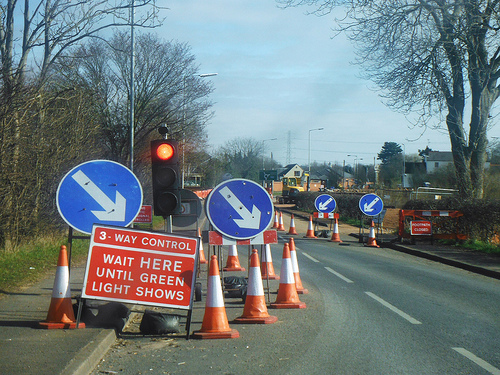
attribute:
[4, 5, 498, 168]
sky — blue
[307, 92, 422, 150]
clouds — white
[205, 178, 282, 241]
sign — blue, white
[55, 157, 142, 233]
sign — blue, white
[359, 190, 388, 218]
sign — blue, white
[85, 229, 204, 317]
sign — red, orange, white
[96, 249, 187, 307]
writing — white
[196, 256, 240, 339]
cone — orange, white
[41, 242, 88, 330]
cone — orange, white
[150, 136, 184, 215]
street light — red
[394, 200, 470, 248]
barricade — orange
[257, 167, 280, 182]
traffic sign — green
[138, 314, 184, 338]
bag — black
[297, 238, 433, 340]
line — white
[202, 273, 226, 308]
stripe — white